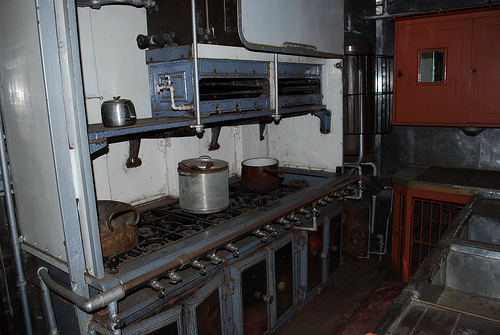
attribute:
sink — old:
[408, 208, 499, 325]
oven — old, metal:
[136, 45, 276, 133]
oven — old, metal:
[272, 55, 344, 115]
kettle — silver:
[236, 152, 288, 194]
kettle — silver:
[166, 148, 238, 222]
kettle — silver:
[93, 190, 147, 262]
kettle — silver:
[97, 87, 140, 129]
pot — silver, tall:
[176, 153, 232, 215]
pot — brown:
[238, 156, 279, 190]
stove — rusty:
[24, 167, 346, 331]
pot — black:
[239, 155, 283, 191]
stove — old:
[105, 149, 344, 250]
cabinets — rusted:
[325, 215, 347, 278]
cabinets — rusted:
[294, 222, 329, 297]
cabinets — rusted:
[269, 232, 299, 324]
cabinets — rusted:
[232, 252, 274, 334]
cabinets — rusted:
[189, 275, 226, 333]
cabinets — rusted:
[124, 301, 188, 333]